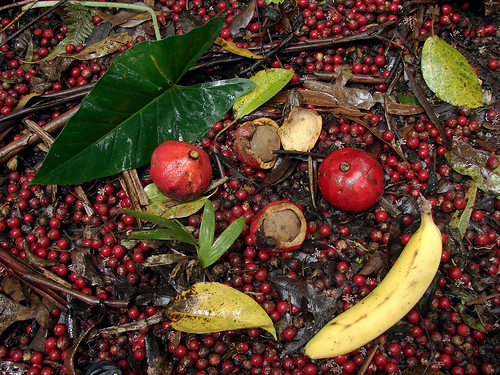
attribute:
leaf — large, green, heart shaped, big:
[47, 19, 252, 162]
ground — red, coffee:
[3, 7, 488, 354]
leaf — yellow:
[165, 273, 282, 347]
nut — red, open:
[253, 194, 313, 253]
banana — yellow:
[305, 205, 452, 357]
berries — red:
[6, 206, 77, 276]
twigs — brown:
[304, 24, 413, 56]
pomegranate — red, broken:
[149, 135, 213, 198]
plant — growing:
[148, 204, 251, 282]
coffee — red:
[438, 305, 494, 362]